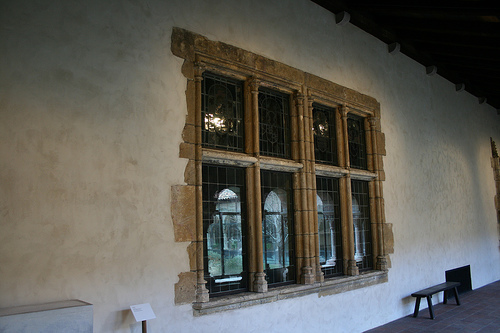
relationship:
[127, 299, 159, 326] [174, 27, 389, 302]
plaque by windows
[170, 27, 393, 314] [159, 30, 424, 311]
rock around window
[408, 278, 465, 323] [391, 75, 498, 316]
chair next to wall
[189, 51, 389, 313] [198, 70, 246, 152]
trim surrounding window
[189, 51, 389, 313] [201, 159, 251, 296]
trim surrounding window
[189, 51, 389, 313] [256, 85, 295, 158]
trim surrounding window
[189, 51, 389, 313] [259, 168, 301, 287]
trim surrounding window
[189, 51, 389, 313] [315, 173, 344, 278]
trim surrounding window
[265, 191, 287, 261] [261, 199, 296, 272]
tree creating reflection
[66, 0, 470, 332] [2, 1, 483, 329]
wall supporting building